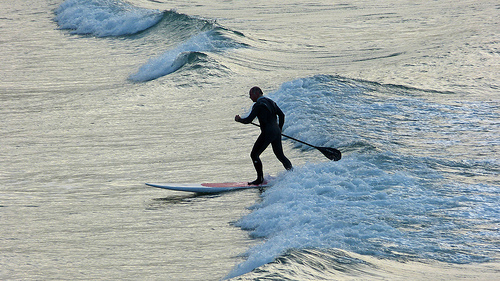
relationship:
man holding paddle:
[235, 80, 296, 182] [234, 111, 346, 163]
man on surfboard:
[232, 85, 297, 185] [149, 161, 274, 208]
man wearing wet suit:
[232, 85, 297, 185] [245, 98, 291, 173]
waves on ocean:
[157, 10, 232, 84] [2, 2, 214, 257]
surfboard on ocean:
[147, 172, 254, 195] [0, 0, 499, 158]